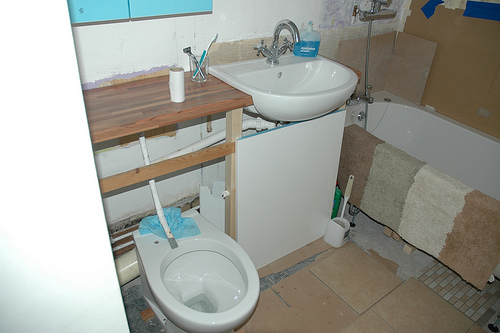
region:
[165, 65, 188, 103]
Almost empty toilet paper role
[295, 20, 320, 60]
Half full hand washing soap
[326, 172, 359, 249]
Toilet brush cleaner,and toilet brush holder, with green toilet cleaner on side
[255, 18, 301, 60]
Faucet on the sink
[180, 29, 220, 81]
Cup holding razor and toothbrush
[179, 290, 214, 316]
Toilet bowl water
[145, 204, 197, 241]
Blue tissue paper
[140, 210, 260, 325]
Toilet with blue paper on top and white pipe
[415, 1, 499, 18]
Blue tape on cardboard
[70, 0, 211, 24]
Bottom of mirror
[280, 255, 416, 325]
Floor is made of tiles.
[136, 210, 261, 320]
Toilet is white color.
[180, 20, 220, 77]
Brush is in stand.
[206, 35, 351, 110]
Sink is white color.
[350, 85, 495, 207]
Tub is white color.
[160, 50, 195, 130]
Tissue roll is in stand.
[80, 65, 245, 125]
Shelf is brown color.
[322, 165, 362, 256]
Cleaning brush is near the tub.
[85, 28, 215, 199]
Wall is white color.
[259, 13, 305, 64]
Faucet is silver color.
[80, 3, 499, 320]
BATHROOM NEEDING REMODELED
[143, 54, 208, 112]
EMPTY TOILET PAPER ROLL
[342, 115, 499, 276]
RUG HANGING ON TUB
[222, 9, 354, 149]
WHITE SINK WITH SOAP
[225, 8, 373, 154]
WHITE SINK WITH BLUE HAND SOAP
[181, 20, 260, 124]
TOOTH BRUSH AND RAZOR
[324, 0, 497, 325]
BATH TUB WITH NO SHOWER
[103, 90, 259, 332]
TOILET WITH NO WATER TANK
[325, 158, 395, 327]
WHITE TOILET SCRUB BRUSH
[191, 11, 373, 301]
SINK WITH NO BATHROOM CUPBOARD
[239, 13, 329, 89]
Silver faucet on sink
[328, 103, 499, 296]
Four panel rug hanging over tub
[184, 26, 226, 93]
Small clear cup with razor and toothbrush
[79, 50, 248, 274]
Tall brown table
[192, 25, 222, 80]
Blue and white toothbrush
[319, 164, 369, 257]
White toilet bowl cleaner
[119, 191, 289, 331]
Small white toilet without a lid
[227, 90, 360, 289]
White square piece of wall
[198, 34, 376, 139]
Half a circle of sink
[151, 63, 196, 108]
Empty roll of toilet paper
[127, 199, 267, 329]
A toilet in a bathroom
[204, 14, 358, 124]
A sink in a bathroom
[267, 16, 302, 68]
The sink's water faucet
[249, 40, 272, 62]
The hot water handle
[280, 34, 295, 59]
The cold water handle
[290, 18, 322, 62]
Liquid soap to the right of the faucet on the sink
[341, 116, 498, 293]
A bath mat sitting on the side of the bathrub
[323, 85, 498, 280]
A bathtub in the bathroom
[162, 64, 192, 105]
A roll of toilet paper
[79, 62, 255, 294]
A table behind the toilet in the bathroom